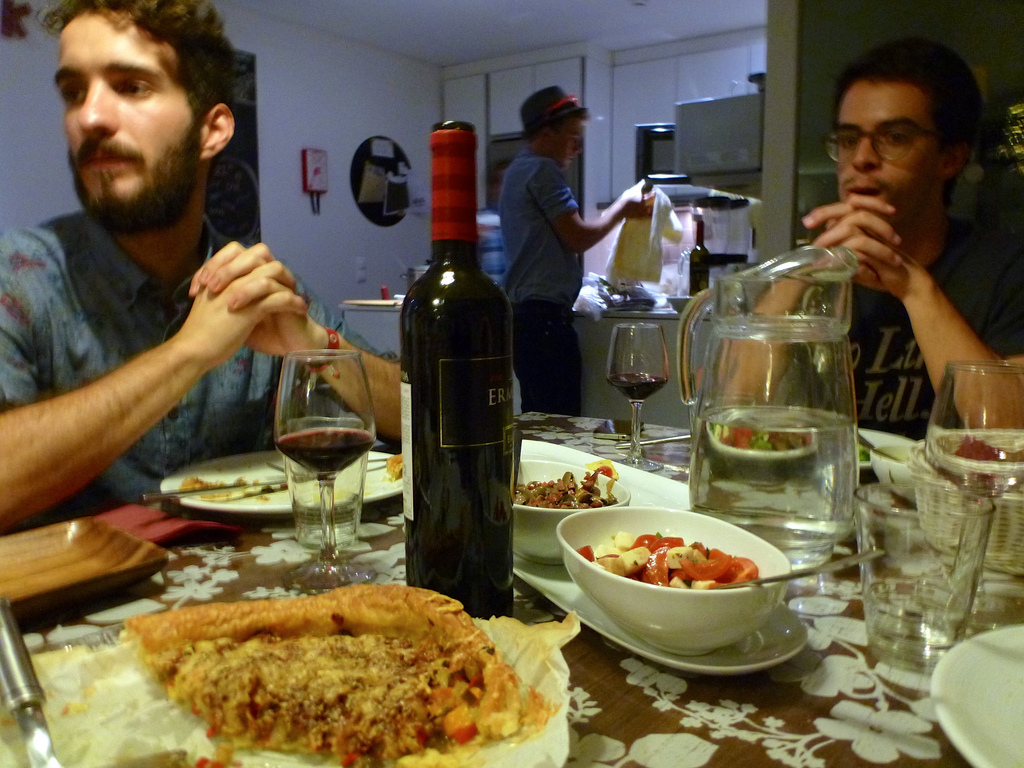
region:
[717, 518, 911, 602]
silver spoon in white bowl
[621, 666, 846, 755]
white flower design on table cloth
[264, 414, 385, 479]
red wine in glass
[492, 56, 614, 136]
hat on man's head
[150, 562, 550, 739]
piece of pie on plate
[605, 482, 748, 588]
tomato and cheese in bowl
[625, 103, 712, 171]
black microwave on wall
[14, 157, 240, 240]
beard on man's face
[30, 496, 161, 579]
small brown wooden bowl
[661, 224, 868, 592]
Pitcher of water on the table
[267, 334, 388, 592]
Wine in the glass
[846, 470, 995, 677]
Glass of water on the table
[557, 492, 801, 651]
White bowl on the plate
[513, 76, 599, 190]
hat on the man's head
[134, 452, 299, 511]
knife on the plate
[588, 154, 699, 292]
Dough in the hand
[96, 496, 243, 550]
red napkin on the table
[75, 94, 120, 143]
it is the nose of the man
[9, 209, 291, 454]
the shirt is blue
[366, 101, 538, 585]
a black wine bottle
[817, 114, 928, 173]
the glasses are clear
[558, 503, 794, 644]
the bowl is white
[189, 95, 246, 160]
it is the ear of the man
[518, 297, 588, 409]
the pants are blue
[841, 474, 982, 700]
a clear glass is on the table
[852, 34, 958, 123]
the hair is black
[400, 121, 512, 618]
the wine bottle is dark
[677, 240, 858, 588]
the water pitcher is made of clear glass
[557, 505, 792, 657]
the food in the white bowl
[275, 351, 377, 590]
the red wine in the clear glass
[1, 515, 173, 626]
the plate is made of wood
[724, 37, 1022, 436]
the man is wearing glasses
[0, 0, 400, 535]
the man has facial hair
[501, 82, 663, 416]
the man is standing up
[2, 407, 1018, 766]
the tablecloth is brown and white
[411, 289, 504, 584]
A bottle of wine on the table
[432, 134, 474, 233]
A red tape on the neck of a bottle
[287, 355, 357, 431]
A glass of wine on a table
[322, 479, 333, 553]
The stem of a wine glass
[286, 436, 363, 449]
Red wine in a glass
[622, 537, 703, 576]
Fruit dessert in a bowl on a table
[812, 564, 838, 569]
A spoon in a bowl of dessert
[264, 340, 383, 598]
red wine in the glass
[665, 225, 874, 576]
pitcher of water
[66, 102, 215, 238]
man has a beard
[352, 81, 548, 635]
bottle of wine with red top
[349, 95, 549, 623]
bottle of wine with red top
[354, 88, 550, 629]
bottle of wine with red top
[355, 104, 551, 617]
bottle of wine with red top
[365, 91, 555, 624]
bottle of wine with red top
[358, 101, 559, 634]
bottle of wine with red top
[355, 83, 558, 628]
bottle of wine with red top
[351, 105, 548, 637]
bottle of wine with red top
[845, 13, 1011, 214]
a person sitting at the table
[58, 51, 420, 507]
a person sitting at the table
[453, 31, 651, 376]
a person in the kitchen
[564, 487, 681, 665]
a bowl on the table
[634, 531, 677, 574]
food in the bowl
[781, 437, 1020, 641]
glasses on the table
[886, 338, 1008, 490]
glasses on the table